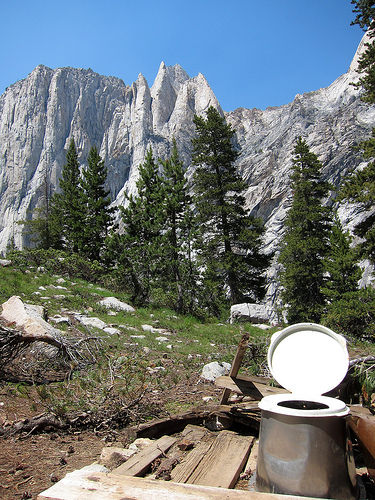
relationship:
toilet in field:
[250, 301, 360, 444] [59, 229, 317, 499]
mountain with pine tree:
[2, 36, 374, 315] [281, 130, 368, 328]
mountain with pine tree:
[2, 36, 374, 315] [194, 108, 266, 301]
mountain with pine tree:
[2, 36, 374, 315] [156, 133, 192, 303]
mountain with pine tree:
[2, 36, 374, 315] [117, 138, 177, 288]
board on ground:
[35, 467, 321, 498] [0, 249, 375, 498]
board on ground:
[109, 431, 178, 481] [0, 249, 375, 498]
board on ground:
[166, 420, 249, 486] [0, 249, 375, 498]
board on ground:
[234, 435, 265, 492] [0, 249, 375, 498]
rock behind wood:
[198, 360, 232, 383] [124, 331, 291, 437]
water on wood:
[233, 469, 261, 489] [234, 439, 272, 494]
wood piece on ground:
[220, 327, 252, 408] [0, 249, 375, 498]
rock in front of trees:
[230, 301, 268, 321] [188, 105, 362, 323]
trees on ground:
[188, 105, 362, 323] [0, 249, 375, 498]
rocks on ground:
[24, 49, 282, 223] [35, 244, 330, 447]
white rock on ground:
[1, 254, 12, 268] [0, 249, 375, 498]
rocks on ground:
[9, 262, 246, 396] [0, 249, 375, 498]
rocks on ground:
[27, 52, 349, 254] [26, 268, 373, 480]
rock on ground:
[127, 334, 151, 340] [2, 251, 368, 419]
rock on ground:
[142, 318, 167, 334] [2, 251, 368, 419]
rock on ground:
[103, 294, 135, 316] [2, 251, 368, 419]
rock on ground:
[80, 312, 120, 335] [2, 251, 368, 419]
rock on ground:
[52, 312, 70, 328] [2, 251, 368, 419]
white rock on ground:
[1, 254, 12, 268] [167, 303, 218, 354]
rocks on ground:
[93, 297, 172, 349] [0, 249, 375, 498]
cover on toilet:
[248, 304, 347, 399] [240, 308, 355, 463]